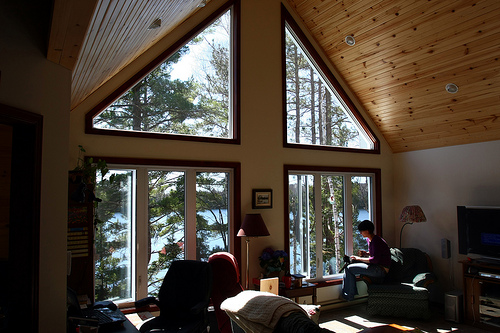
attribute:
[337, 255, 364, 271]
cat — black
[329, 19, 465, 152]
ceiling — wooden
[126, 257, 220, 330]
seat — black, empty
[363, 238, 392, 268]
shirt — purple